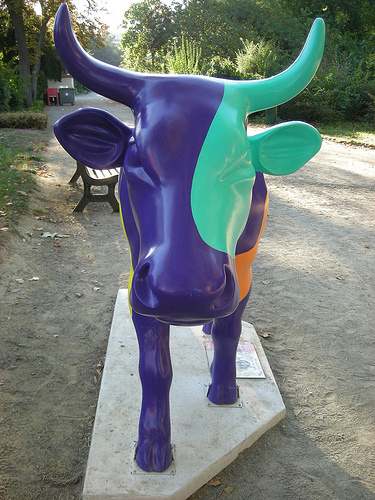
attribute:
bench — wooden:
[69, 161, 120, 214]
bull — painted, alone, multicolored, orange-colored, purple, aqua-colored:
[51, 1, 326, 473]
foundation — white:
[81, 287, 287, 499]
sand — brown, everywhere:
[2, 102, 374, 500]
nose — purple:
[128, 261, 238, 321]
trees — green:
[120, 1, 374, 119]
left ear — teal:
[250, 118, 322, 176]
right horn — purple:
[53, 2, 132, 110]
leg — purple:
[130, 311, 174, 435]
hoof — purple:
[208, 381, 242, 404]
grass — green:
[0, 142, 45, 251]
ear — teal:
[250, 119, 322, 176]